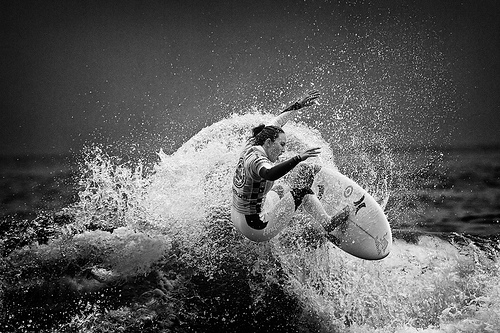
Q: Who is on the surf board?
A: The man is on the surf board.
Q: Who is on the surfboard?
A: The man is on the surf board.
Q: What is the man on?
A: The man is on the surfboard.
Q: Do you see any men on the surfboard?
A: Yes, there is a man on the surfboard.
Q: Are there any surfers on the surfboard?
A: No, there is a man on the surfboard.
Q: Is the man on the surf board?
A: Yes, the man is on the surf board.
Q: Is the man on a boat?
A: No, the man is on the surf board.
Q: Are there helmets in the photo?
A: No, there are no helmets.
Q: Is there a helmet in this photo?
A: No, there are no helmets.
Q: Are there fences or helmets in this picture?
A: No, there are no helmets or fences.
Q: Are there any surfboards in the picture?
A: Yes, there is a surfboard.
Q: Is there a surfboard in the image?
A: Yes, there is a surfboard.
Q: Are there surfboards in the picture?
A: Yes, there is a surfboard.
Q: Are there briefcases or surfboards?
A: Yes, there is a surfboard.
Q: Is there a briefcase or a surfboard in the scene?
A: Yes, there is a surfboard.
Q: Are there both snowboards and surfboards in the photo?
A: No, there is a surfboard but no snowboards.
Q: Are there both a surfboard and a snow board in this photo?
A: No, there is a surfboard but no snowboards.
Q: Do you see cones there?
A: No, there are no cones.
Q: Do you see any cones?
A: No, there are no cones.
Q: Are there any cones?
A: No, there are no cones.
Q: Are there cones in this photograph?
A: No, there are no cones.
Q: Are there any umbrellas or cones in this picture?
A: No, there are no cones or umbrellas.